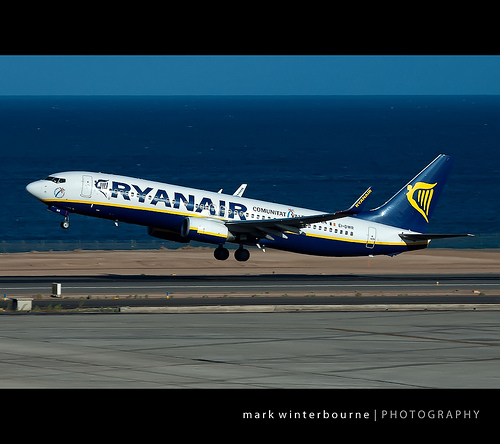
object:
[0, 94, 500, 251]
ocean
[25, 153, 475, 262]
jet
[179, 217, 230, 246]
engines